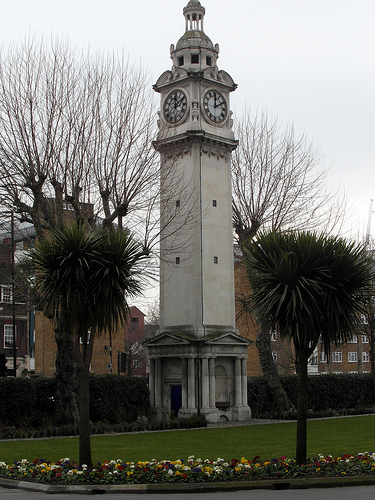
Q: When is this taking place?
A: Daytime.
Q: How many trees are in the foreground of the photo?
A: Two.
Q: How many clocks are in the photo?
A: Two.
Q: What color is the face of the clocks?
A: Black and white.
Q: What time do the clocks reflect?
A: 2:00.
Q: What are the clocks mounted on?
A: White stone tower.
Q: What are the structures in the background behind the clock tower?
A: Buildings.